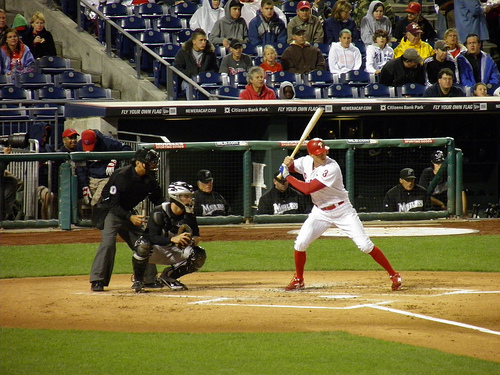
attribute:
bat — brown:
[279, 102, 323, 183]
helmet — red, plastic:
[305, 137, 330, 155]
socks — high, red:
[284, 246, 400, 277]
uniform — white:
[292, 159, 370, 249]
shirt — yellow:
[396, 39, 434, 60]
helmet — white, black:
[167, 179, 195, 213]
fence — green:
[11, 147, 456, 218]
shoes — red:
[288, 276, 401, 289]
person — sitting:
[178, 31, 216, 74]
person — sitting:
[222, 37, 254, 73]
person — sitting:
[404, 3, 432, 36]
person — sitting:
[465, 37, 491, 82]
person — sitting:
[294, 3, 325, 44]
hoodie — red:
[243, 81, 274, 99]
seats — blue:
[12, 13, 483, 95]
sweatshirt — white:
[365, 41, 395, 73]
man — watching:
[435, 67, 467, 98]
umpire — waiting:
[99, 141, 162, 286]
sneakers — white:
[285, 266, 402, 293]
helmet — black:
[130, 147, 162, 180]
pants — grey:
[93, 204, 150, 287]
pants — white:
[291, 199, 375, 257]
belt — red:
[310, 200, 349, 210]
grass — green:
[10, 327, 442, 372]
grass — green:
[12, 233, 498, 266]